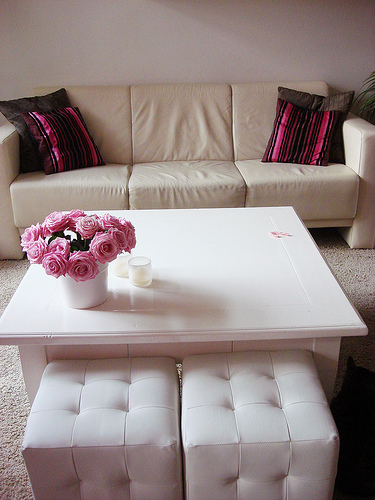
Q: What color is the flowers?
A: Pink.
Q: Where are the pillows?
A: On the couch.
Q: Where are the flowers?
A: On the table.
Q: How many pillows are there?
A: Four.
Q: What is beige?
A: Couch.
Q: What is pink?
A: Flowers.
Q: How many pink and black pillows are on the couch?
A: Two.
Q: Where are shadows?
A: On the table.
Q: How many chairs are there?
A: Two.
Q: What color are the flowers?
A: Pink.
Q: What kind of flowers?
A: Roses.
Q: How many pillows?
A: Four.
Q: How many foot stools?
A: Two.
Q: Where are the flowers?
A: On the table.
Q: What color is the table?
A: White.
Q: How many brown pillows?
A: Two.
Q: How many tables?
A: One.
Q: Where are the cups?
A: On the table.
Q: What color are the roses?
A: Pink.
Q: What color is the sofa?
A: White.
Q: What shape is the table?
A: Square.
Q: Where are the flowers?
A: On the corner.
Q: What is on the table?
A: Flowers.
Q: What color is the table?
A: White.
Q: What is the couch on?
A: Carpet.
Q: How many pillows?
A: 4.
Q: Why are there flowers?
A: Decoration.